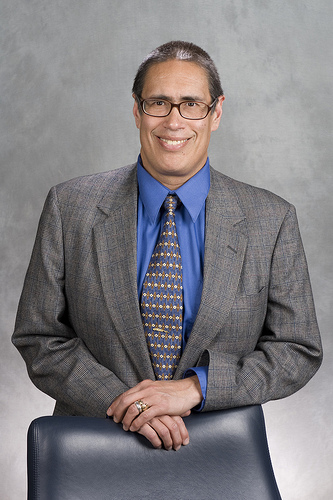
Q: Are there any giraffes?
A: No, there are no giraffes.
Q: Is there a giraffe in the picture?
A: No, there are no giraffes.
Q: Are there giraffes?
A: No, there are no giraffes.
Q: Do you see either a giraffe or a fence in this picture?
A: No, there are no giraffes or fences.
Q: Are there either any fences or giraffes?
A: No, there are no giraffes or fences.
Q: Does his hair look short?
A: Yes, the hair is short.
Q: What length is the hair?
A: The hair is short.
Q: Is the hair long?
A: No, the hair is short.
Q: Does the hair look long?
A: No, the hair is short.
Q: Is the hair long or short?
A: The hair is short.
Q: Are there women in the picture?
A: No, there are no women.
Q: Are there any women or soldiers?
A: No, there are no women or soldiers.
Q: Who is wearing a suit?
A: The man is wearing a suit.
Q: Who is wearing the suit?
A: The man is wearing a suit.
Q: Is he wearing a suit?
A: Yes, the man is wearing a suit.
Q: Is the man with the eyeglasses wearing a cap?
A: No, the man is wearing a suit.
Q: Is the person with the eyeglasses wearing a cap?
A: No, the man is wearing a suit.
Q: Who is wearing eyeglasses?
A: The man is wearing eyeglasses.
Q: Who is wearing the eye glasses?
A: The man is wearing eyeglasses.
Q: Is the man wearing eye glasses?
A: Yes, the man is wearing eye glasses.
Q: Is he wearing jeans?
A: No, the man is wearing eye glasses.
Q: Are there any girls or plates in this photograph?
A: No, there are no girls or plates.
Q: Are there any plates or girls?
A: No, there are no girls or plates.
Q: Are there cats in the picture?
A: No, there are no cats.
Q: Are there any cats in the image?
A: No, there are no cats.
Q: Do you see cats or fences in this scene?
A: No, there are no cats or fences.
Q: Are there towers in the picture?
A: No, there are no towers.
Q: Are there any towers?
A: No, there are no towers.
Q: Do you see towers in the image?
A: No, there are no towers.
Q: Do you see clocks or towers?
A: No, there are no towers or clocks.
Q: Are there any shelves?
A: No, there are no shelves.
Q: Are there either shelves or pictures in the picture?
A: No, there are no shelves or pictures.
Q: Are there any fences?
A: No, there are no fences.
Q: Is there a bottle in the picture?
A: No, there are no bottles.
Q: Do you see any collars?
A: Yes, there is a collar.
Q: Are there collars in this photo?
A: Yes, there is a collar.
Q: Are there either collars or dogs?
A: Yes, there is a collar.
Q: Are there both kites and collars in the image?
A: No, there is a collar but no kites.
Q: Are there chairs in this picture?
A: Yes, there is a chair.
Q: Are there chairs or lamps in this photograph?
A: Yes, there is a chair.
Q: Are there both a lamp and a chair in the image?
A: No, there is a chair but no lamps.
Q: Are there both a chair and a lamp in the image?
A: No, there is a chair but no lamps.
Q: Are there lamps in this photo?
A: No, there are no lamps.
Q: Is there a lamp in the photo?
A: No, there are no lamps.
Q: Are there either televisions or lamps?
A: No, there are no lamps or televisions.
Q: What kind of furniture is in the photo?
A: The furniture is a chair.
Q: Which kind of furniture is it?
A: The piece of furniture is a chair.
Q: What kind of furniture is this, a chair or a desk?
A: This is a chair.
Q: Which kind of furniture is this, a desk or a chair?
A: This is a chair.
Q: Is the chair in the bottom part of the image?
A: Yes, the chair is in the bottom of the image.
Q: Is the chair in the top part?
A: No, the chair is in the bottom of the image.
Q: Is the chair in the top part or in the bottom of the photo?
A: The chair is in the bottom of the image.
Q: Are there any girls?
A: No, there are no girls.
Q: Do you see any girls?
A: No, there are no girls.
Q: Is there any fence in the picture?
A: No, there are no fences.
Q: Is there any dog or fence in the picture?
A: No, there are no fences or dogs.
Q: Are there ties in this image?
A: Yes, there is a tie.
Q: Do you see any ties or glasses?
A: Yes, there is a tie.